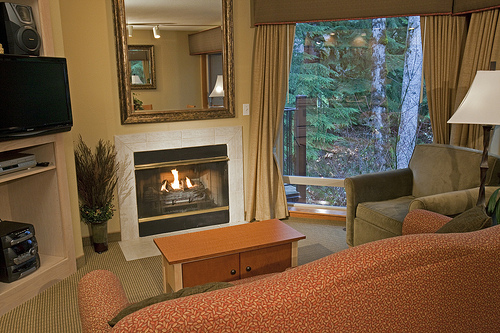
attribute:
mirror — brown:
[112, 2, 236, 122]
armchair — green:
[345, 128, 491, 248]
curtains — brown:
[245, 23, 295, 222]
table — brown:
[146, 213, 306, 290]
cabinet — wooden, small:
[190, 259, 299, 289]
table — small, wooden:
[163, 227, 283, 261]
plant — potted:
[71, 130, 139, 261]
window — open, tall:
[282, 17, 433, 212]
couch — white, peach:
[75, 219, 498, 331]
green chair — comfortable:
[347, 144, 499, 236]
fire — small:
[156, 167, 198, 191]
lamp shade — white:
[446, 70, 499, 124]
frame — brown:
[113, 4, 129, 116]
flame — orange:
[168, 168, 183, 189]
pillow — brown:
[430, 198, 498, 254]